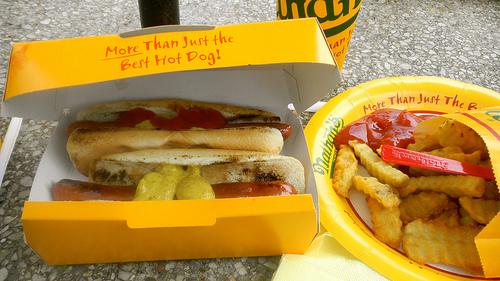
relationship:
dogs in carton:
[65, 95, 300, 199] [10, 10, 338, 257]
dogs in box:
[65, 123, 292, 141] [6, 18, 344, 270]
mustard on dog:
[132, 165, 215, 202] [55, 171, 117, 199]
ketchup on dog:
[127, 99, 221, 128] [54, 177, 122, 200]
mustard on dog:
[132, 165, 215, 202] [54, 177, 122, 200]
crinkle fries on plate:
[329, 119, 499, 274] [314, 76, 484, 259]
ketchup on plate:
[333, 108, 423, 154] [344, 100, 410, 140]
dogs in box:
[65, 123, 292, 141] [0, 16, 340, 268]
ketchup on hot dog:
[116, 105, 228, 130] [60, 101, 289, 141]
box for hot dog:
[0, 16, 340, 268] [48, 90, 298, 201]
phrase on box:
[100, 27, 241, 78] [0, 16, 340, 268]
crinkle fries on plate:
[324, 123, 489, 273] [307, 69, 497, 279]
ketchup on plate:
[333, 108, 423, 154] [307, 69, 497, 279]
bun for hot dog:
[61, 96, 282, 166] [69, 117, 291, 137]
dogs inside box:
[65, 123, 292, 141] [6, 18, 344, 270]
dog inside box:
[52, 179, 297, 201] [6, 18, 344, 270]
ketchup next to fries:
[337, 100, 421, 151] [323, 115, 490, 279]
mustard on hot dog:
[134, 170, 212, 204] [34, 143, 307, 201]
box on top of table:
[6, 18, 344, 270] [7, 6, 484, 278]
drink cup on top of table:
[276, 0, 362, 78] [7, 6, 484, 278]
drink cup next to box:
[276, 0, 362, 78] [0, 16, 340, 268]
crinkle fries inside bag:
[329, 119, 499, 274] [443, 105, 499, 205]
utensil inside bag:
[371, 140, 499, 187] [434, 96, 498, 184]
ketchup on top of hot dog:
[116, 105, 228, 130] [65, 95, 295, 159]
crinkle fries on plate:
[329, 119, 499, 274] [307, 69, 497, 279]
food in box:
[47, 92, 307, 201] [6, 18, 344, 270]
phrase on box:
[104, 31, 232, 72] [6, 18, 344, 270]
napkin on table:
[270, 228, 401, 279] [7, 6, 484, 278]